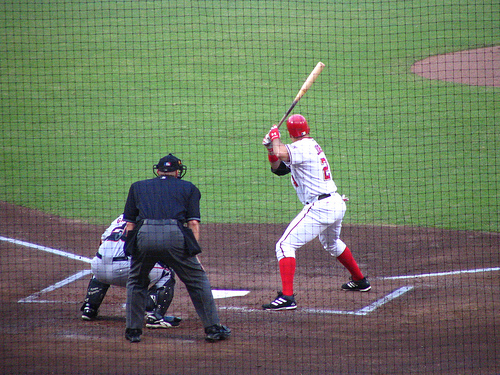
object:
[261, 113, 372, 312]
player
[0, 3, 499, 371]
field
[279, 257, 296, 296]
sock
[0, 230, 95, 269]
line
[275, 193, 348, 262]
pants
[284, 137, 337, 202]
shirt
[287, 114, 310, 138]
helmet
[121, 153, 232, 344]
umpire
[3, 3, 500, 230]
grass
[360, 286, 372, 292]
cleat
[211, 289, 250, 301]
home plate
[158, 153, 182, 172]
hat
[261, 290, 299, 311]
shoe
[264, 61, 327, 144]
bat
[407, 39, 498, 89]
mound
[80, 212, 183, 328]
man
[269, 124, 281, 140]
hand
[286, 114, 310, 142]
head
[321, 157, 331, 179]
number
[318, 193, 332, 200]
belt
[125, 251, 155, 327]
leg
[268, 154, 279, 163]
wristband